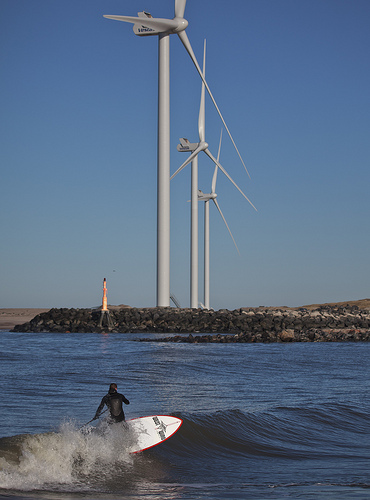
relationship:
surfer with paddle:
[94, 381, 132, 432] [75, 405, 113, 437]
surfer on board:
[94, 381, 132, 432] [101, 411, 185, 458]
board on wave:
[101, 411, 185, 458] [1, 397, 370, 500]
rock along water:
[303, 329, 317, 340] [1, 325, 369, 498]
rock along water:
[350, 307, 362, 317] [1, 325, 369, 498]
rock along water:
[257, 320, 278, 330] [1, 325, 369, 498]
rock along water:
[149, 311, 163, 323] [1, 325, 369, 498]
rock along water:
[127, 307, 143, 317] [1, 325, 369, 498]